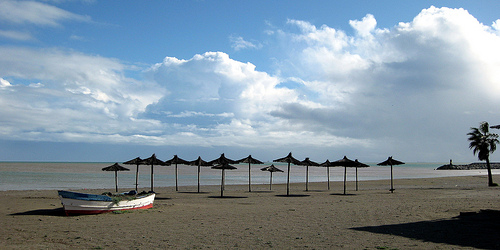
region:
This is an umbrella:
[370, 140, 413, 215]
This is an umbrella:
[348, 149, 363, 213]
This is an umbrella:
[331, 146, 356, 203]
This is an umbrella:
[318, 154, 333, 202]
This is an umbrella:
[295, 146, 321, 202]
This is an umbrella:
[280, 147, 299, 203]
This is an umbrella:
[256, 153, 283, 196]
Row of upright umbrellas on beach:
[103, 150, 404, 195]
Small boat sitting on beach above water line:
[55, 188, 157, 215]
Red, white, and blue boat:
[56, 187, 157, 215]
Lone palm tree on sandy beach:
[466, 122, 498, 186]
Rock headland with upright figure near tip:
[435, 158, 499, 170]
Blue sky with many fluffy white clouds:
[2, 1, 499, 159]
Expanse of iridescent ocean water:
[1, 159, 498, 191]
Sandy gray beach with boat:
[1, 173, 499, 248]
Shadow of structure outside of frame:
[348, 208, 499, 249]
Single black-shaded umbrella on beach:
[377, 155, 404, 192]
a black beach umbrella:
[103, 161, 130, 191]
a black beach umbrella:
[124, 155, 146, 192]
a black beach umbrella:
[140, 152, 169, 192]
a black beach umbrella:
[165, 153, 188, 190]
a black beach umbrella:
[188, 154, 210, 189]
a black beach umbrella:
[212, 160, 237, 195]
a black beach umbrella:
[236, 152, 262, 191]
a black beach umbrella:
[259, 163, 283, 191]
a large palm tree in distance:
[467, 120, 498, 189]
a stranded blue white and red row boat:
[55, 187, 157, 217]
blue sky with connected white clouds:
[5, 5, 494, 160]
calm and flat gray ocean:
[5, 158, 497, 191]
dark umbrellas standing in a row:
[99, 149, 407, 201]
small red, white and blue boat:
[55, 182, 156, 217]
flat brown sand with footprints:
[6, 172, 498, 243]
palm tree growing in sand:
[462, 115, 497, 194]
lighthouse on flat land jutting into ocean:
[433, 155, 497, 174]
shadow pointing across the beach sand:
[339, 202, 494, 244]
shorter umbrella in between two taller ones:
[235, 146, 302, 199]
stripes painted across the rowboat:
[53, 183, 157, 214]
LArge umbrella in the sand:
[103, 149, 125, 206]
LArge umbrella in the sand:
[125, 146, 146, 196]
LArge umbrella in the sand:
[142, 146, 165, 193]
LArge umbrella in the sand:
[170, 146, 193, 191]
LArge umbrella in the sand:
[186, 143, 206, 200]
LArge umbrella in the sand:
[210, 155, 232, 203]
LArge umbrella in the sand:
[240, 149, 259, 187]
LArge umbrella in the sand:
[250, 146, 292, 207]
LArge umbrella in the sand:
[274, 143, 304, 195]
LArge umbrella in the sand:
[294, 143, 317, 198]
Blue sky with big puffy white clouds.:
[1, 1, 498, 161]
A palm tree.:
[467, 122, 498, 187]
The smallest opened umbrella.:
[260, 163, 284, 191]